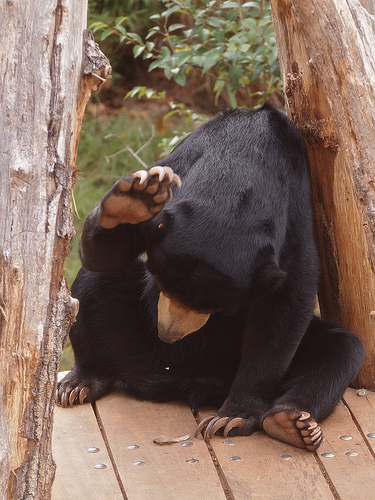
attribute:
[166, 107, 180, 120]
leaf — green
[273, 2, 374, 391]
trunk — worn, here, a tree, tree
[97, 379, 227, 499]
board — wood, brown, wooden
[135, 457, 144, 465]
bolt — metal, grey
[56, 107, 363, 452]
bear — sitting, black, here, animal, looking down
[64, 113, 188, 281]
grass — tall